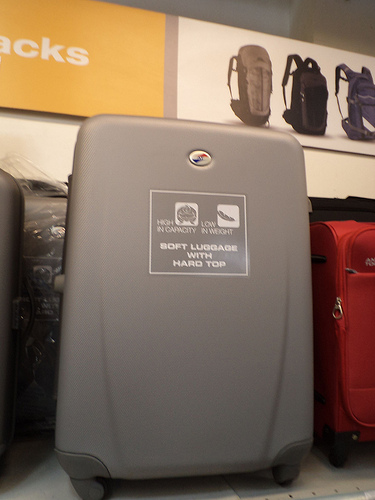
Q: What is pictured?
A: Luggage.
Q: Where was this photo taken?
A: At a store.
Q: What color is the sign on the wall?
A: Yellow, grey, and white.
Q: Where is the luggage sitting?
A: On a shelf.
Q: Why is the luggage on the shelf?
A: It is for sale.